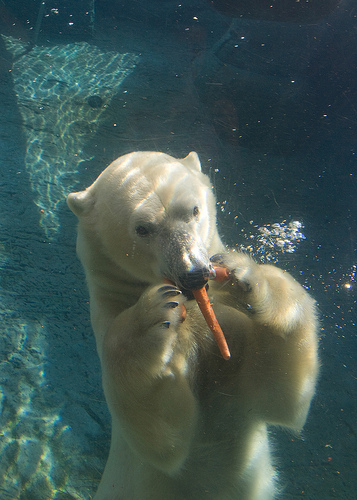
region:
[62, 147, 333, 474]
a polar bear eating a carrot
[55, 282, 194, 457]
the right arm of a polar bear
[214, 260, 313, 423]
the left arm of a polar bear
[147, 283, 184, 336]
the claws of a polar bear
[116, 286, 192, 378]
the paw of a polar bear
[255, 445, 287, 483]
the fur of a polar bear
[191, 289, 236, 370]
a long orange carrot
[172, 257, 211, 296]
the nose of a polar bear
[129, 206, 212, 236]
the eyes of a polar bear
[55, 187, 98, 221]
the ear of a polar bear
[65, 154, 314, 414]
the bear is eating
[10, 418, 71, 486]
reflection on the water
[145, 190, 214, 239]
eyes on the bear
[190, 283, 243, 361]
the carrot is long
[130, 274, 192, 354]
paw of the bear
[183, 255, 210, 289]
nose of the bear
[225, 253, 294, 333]
paw of the bear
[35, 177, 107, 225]
ear of the bear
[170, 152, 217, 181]
ear of the bear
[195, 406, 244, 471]
the fur is white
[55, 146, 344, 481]
A polar bear submerged in water eating carrot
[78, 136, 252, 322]
the head of a bear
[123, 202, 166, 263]
the eye of a bear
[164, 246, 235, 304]
the nose of a bear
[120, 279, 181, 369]
the claws of a bear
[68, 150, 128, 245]
the ear of a bear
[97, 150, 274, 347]
the face of a bear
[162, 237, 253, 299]
the mouth of a bear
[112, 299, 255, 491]
the arm of a bear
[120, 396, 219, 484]
the elbow of a bear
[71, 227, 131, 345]
the neck of a bear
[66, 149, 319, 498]
a white bear under water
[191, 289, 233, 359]
a carrot in the bear's mouth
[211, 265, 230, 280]
a piece of carrot in the bear's hand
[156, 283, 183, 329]
the bear's black claws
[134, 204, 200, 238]
the bear's two eye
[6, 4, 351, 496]
a white bear eating carrots under the water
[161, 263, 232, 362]
three pieces of carrots in the bear's mouth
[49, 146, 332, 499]
a bear eating three pieces of carrots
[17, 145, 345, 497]
a bear under water eating carrots